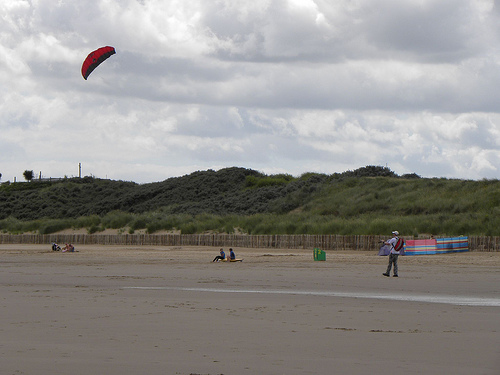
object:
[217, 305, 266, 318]
mark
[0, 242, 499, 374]
ground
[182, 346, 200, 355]
mark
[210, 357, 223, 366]
mark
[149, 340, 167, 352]
mark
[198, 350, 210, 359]
mark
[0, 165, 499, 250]
hill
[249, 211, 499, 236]
greenery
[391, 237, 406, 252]
backpack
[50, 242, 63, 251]
people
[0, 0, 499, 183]
sky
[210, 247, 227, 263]
people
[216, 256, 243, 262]
blanket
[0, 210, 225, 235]
grass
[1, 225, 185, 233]
sand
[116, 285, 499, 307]
patch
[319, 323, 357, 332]
mark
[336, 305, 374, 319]
mark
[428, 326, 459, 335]
mark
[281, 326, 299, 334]
mark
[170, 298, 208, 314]
spotted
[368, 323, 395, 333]
mark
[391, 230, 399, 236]
head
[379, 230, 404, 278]
man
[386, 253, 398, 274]
pants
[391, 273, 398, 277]
shoes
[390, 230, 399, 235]
hat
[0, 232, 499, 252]
fence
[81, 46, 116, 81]
kite